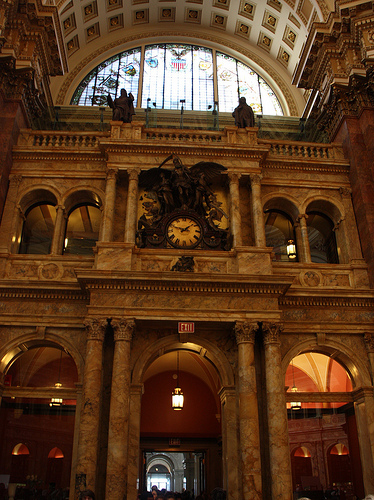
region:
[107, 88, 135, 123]
statues mounted on the balcony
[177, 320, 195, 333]
an exit sign above the archway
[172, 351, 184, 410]
a ceiling lamp attached to the ceiling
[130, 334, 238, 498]
an archway entrance to the building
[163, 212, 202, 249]
a clock above the exit sign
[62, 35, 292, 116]
a stained glass window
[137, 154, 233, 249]
a statue around the clock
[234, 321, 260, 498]
marble columns on each side of the archway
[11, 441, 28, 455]
orange and white canopy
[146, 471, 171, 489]
bright sunlight streaming in through the doors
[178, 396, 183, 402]
bottom of a bulb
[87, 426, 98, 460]
edge of a wall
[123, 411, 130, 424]
section of a pillar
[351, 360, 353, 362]
roof of a house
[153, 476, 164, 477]
section of a window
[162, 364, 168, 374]
roof of a palace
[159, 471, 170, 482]
section of a window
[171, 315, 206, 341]
a red and white exit sign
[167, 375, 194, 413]
a light hanging from the ceiling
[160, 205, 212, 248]
a clock above the archway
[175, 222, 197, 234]
black hands on the clock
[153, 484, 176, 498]
a crowd of people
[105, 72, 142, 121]
a statue near the window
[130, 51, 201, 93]
an arched stained glass window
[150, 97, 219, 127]
cameras set up on tripods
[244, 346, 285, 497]
brown marble columns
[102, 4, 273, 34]
decorative square on the ceiling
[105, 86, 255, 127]
Two statues at the top of the church by the windows.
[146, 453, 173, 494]
Arched doorway past the people in the church.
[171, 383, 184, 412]
Illuminated light hanging from the ceiling.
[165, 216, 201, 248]
A large old clock face in the church.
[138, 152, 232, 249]
Angels and reapers surrounding a clock.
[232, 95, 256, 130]
A statue high on the right.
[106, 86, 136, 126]
Statue high on the left.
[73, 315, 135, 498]
Two marbled columns on the left.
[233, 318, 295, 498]
Two marbled columns on the right bottom.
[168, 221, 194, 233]
Black hands on a clock.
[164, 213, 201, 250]
The clock is white.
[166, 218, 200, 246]
Hands on clock are black.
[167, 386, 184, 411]
The light is on.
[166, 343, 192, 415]
The light is hanging.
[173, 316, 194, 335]
Exit sign above door.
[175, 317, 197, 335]
exit sign is red.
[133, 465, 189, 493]
Light coming through windows.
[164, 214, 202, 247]
Numbers are roman numeral.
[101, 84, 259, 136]
Sculptures in the building.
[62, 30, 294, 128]
Window is half circle.